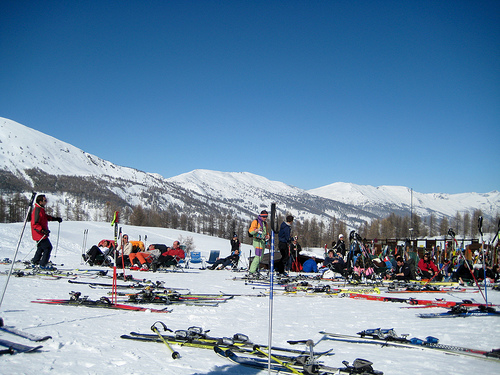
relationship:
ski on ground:
[37, 298, 168, 312] [0, 221, 499, 375]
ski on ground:
[29, 300, 173, 313] [0, 221, 499, 375]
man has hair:
[31, 194, 62, 270] [36, 194, 46, 204]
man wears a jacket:
[31, 194, 62, 270] [31, 202, 54, 241]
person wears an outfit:
[248, 210, 270, 277] [249, 217, 271, 273]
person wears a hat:
[248, 210, 270, 277] [259, 210, 269, 217]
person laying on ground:
[129, 244, 162, 272] [0, 221, 499, 375]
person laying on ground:
[82, 240, 110, 267] [0, 221, 499, 375]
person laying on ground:
[152, 240, 185, 272] [0, 221, 499, 375]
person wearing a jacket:
[152, 240, 185, 272] [162, 246, 184, 261]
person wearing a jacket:
[129, 244, 162, 272] [140, 248, 161, 261]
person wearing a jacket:
[82, 240, 110, 267] [98, 246, 110, 255]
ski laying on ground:
[37, 298, 168, 312] [0, 221, 499, 375]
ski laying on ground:
[29, 300, 173, 313] [0, 221, 499, 375]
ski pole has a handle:
[268, 203, 280, 375] [270, 203, 276, 231]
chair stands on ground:
[186, 251, 204, 268] [0, 221, 499, 375]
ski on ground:
[120, 335, 322, 363] [0, 221, 499, 375]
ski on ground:
[130, 331, 334, 355] [0, 221, 499, 375]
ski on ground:
[0, 318, 52, 343] [0, 221, 499, 375]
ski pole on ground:
[268, 203, 280, 375] [0, 221, 499, 375]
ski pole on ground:
[151, 321, 181, 361] [0, 221, 499, 375]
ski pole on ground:
[252, 344, 304, 375] [0, 221, 499, 375]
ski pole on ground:
[447, 228, 486, 303] [0, 221, 499, 375]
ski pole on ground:
[478, 216, 487, 309] [0, 221, 499, 375]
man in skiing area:
[31, 194, 62, 270] [0, 220, 499, 374]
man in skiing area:
[206, 249, 239, 270] [0, 220, 499, 374]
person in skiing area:
[248, 210, 270, 277] [0, 220, 499, 374]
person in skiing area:
[152, 240, 185, 272] [0, 220, 499, 374]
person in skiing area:
[129, 244, 162, 272] [0, 220, 499, 374]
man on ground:
[31, 194, 62, 270] [0, 221, 499, 375]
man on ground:
[206, 249, 239, 270] [0, 221, 499, 375]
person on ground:
[248, 210, 270, 277] [0, 221, 499, 375]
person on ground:
[152, 240, 185, 272] [0, 221, 499, 375]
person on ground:
[129, 244, 162, 272] [0, 221, 499, 375]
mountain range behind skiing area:
[0, 116, 499, 241] [0, 220, 499, 374]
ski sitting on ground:
[0, 318, 52, 343] [0, 221, 499, 375]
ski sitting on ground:
[29, 300, 173, 313] [0, 221, 499, 375]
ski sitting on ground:
[37, 298, 168, 312] [0, 221, 499, 375]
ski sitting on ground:
[120, 335, 322, 363] [0, 221, 499, 375]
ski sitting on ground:
[130, 331, 334, 355] [0, 221, 499, 375]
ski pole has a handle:
[447, 228, 486, 303] [448, 230, 454, 238]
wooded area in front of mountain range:
[1, 192, 500, 250] [0, 116, 499, 241]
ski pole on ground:
[118, 226, 126, 280] [0, 221, 499, 375]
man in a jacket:
[31, 194, 62, 270] [31, 202, 54, 241]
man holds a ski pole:
[31, 194, 62, 270] [54, 222, 61, 258]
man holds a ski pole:
[31, 194, 62, 270] [21, 234, 46, 263]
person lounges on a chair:
[152, 240, 185, 272] [159, 244, 188, 272]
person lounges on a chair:
[129, 244, 162, 272] [136, 244, 168, 272]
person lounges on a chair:
[107, 234, 132, 268] [110, 241, 145, 267]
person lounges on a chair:
[82, 240, 110, 267] [84, 240, 113, 267]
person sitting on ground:
[152, 240, 185, 272] [0, 221, 499, 375]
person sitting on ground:
[129, 244, 162, 272] [0, 221, 499, 375]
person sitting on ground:
[107, 234, 132, 268] [0, 221, 499, 375]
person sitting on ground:
[82, 240, 110, 267] [0, 221, 499, 375]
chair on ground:
[186, 251, 204, 268] [0, 221, 499, 375]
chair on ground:
[203, 250, 219, 267] [0, 221, 499, 375]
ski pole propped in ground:
[447, 228, 486, 303] [0, 221, 499, 375]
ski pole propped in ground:
[478, 216, 487, 309] [0, 221, 499, 375]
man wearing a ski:
[31, 194, 62, 270] [33, 268, 76, 272]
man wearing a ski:
[31, 194, 62, 270] [4, 267, 35, 270]